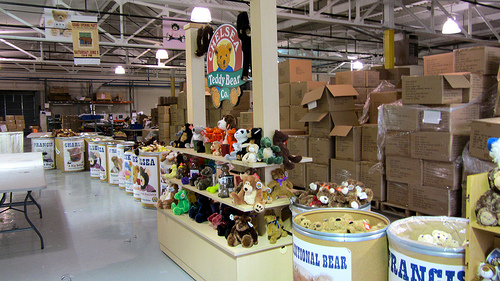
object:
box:
[398, 73, 473, 106]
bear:
[340, 222, 351, 233]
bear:
[328, 213, 343, 224]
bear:
[354, 218, 379, 230]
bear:
[327, 225, 339, 232]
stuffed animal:
[272, 131, 302, 171]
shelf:
[166, 146, 314, 168]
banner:
[205, 23, 245, 107]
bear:
[169, 188, 192, 215]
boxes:
[300, 83, 359, 113]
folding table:
[0, 152, 48, 250]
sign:
[162, 17, 190, 51]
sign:
[69, 16, 103, 64]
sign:
[44, 7, 78, 40]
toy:
[307, 194, 334, 207]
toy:
[298, 218, 310, 230]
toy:
[435, 233, 450, 246]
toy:
[414, 231, 437, 247]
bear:
[263, 214, 288, 244]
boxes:
[377, 99, 427, 132]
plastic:
[375, 103, 395, 161]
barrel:
[289, 207, 391, 280]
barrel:
[291, 189, 371, 219]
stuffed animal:
[315, 185, 332, 204]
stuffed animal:
[449, 236, 459, 248]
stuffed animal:
[357, 187, 372, 204]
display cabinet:
[465, 170, 500, 280]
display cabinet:
[156, 141, 313, 280]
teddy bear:
[193, 162, 213, 192]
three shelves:
[140, 130, 290, 277]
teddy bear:
[206, 42, 243, 106]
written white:
[206, 73, 243, 102]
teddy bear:
[46, 10, 74, 37]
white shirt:
[54, 20, 68, 28]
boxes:
[384, 156, 427, 186]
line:
[0, 58, 188, 71]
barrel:
[384, 215, 469, 280]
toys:
[372, 223, 382, 232]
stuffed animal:
[265, 165, 295, 199]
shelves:
[162, 178, 293, 213]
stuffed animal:
[227, 212, 257, 249]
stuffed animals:
[170, 122, 195, 147]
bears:
[225, 128, 252, 159]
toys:
[292, 189, 309, 206]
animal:
[258, 135, 284, 165]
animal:
[264, 214, 289, 243]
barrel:
[53, 137, 86, 172]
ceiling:
[0, 0, 500, 87]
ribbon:
[274, 176, 287, 188]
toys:
[231, 172, 271, 214]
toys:
[189, 192, 220, 224]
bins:
[29, 136, 56, 170]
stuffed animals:
[157, 182, 179, 209]